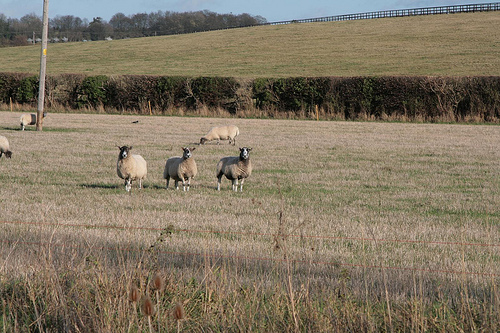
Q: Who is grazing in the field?
A: Sheep.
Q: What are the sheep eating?
A: Grass.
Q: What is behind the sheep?
A: Hedge fence.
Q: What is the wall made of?
A: Hedges.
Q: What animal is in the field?
A: Sheep.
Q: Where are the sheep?
A: Field.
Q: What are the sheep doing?
A: Grazing.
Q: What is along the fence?
A: Hedge.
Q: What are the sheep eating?
A: Grass.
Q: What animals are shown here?
A: Sheep.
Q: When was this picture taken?
A: Daytime.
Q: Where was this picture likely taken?
A: A farm.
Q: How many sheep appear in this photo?
A: Six.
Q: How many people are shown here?
A: Zero.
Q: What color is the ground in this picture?
A: Brown.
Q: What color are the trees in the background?
A: Green.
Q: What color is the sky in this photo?
A: Blue.